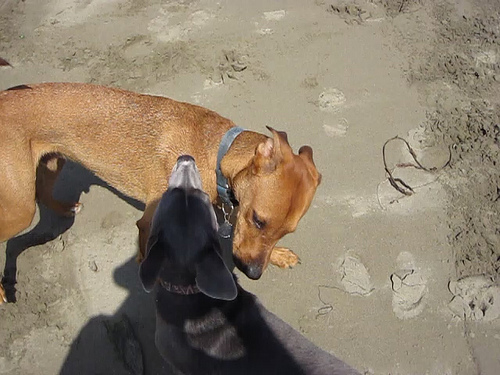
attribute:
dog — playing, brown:
[0, 78, 329, 299]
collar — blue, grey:
[207, 123, 254, 214]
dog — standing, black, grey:
[114, 152, 373, 374]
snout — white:
[157, 149, 219, 199]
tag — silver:
[217, 215, 240, 239]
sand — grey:
[147, 12, 482, 98]